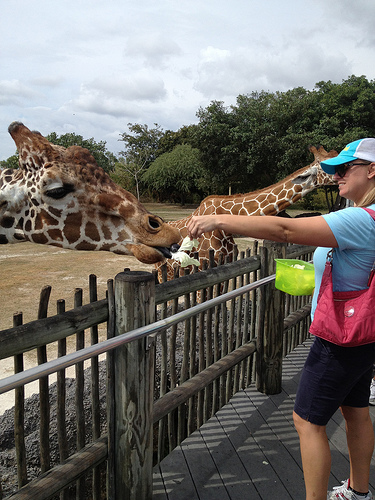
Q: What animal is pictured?
A: Giraffe.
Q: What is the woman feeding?
A: Giraffe.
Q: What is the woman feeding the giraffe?
A: Lettuce.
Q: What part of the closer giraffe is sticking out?
A: Tongue.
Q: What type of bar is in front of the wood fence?
A: Metal.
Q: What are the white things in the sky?
A: Clouds.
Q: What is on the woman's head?
A: Cap.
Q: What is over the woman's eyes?
A: Sunglasses.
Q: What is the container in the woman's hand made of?
A: Plastic.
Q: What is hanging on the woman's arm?
A: Red bag.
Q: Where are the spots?
A: On the giraffe.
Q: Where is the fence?
A: In front of the giraffes.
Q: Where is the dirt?
A: On the ground.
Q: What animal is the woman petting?
A: A giraffe.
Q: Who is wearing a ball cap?
A: A woman.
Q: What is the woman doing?
A: Feeding a giraffe.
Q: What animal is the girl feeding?
A: Giraffe.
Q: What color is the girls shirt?
A: Blue.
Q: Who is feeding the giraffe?
A: A girl.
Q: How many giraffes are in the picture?
A: 2.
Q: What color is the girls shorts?
A: Navy.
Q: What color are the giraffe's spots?
A: Brown.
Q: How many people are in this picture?
A: 1.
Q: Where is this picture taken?
A: Zoo.